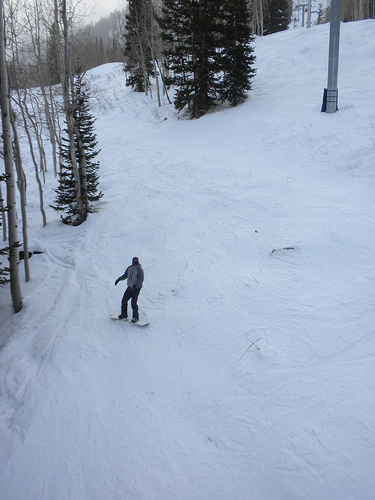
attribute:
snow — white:
[3, 88, 374, 499]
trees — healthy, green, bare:
[0, 1, 268, 274]